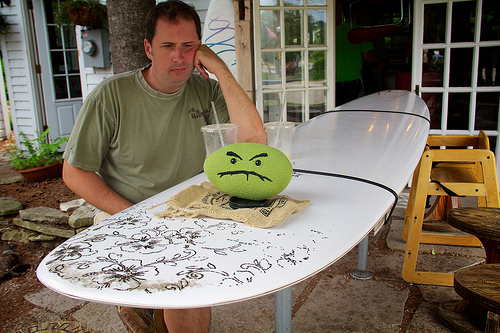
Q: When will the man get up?
A: After he finishes with the surfboard.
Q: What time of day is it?
A: Daytime.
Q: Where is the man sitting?
A: In front of a surfboard.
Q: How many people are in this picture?
A: One.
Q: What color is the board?
A: Black and white.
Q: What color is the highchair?
A: Brown.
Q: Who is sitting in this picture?
A: A man.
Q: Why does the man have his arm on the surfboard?
A: Because he is tired.